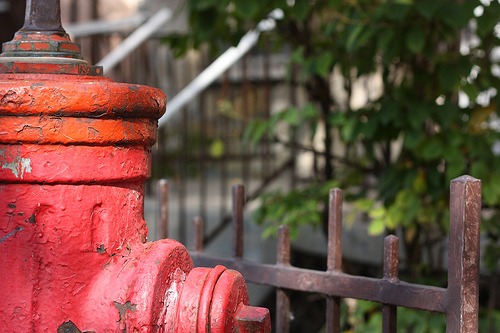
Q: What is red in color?
A: The hydrant.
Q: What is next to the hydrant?
A: Fence.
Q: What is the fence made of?
A: Metal.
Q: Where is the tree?
A: In the distance.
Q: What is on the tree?
A: Leaves.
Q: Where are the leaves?
A: On the tree.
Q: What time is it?
A: Afternoon.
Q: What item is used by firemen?
A: Hydrant.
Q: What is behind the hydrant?
A: Fence.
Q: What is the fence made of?
A: Iron.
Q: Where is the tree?
A: Behind the fence.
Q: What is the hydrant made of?
A: Metal.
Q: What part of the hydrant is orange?
A: The top.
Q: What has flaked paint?
A: The hydrant.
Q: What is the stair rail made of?
A: Metal.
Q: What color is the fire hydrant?
A: Red.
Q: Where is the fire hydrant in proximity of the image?
A: The left.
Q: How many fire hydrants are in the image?
A: One.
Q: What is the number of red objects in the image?
A: One.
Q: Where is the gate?
A: Behind the hydrant.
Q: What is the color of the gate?
A: Brown.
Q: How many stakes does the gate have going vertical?
A: Seven.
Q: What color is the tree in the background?
A: Green.